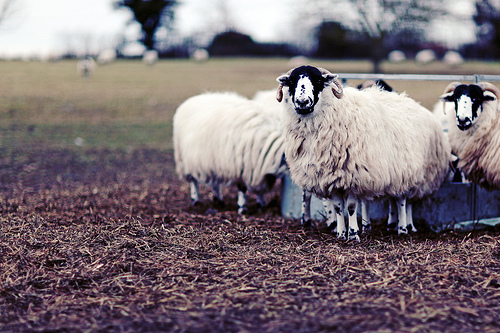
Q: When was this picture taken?
A: During the day.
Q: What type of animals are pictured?
A: Sheep.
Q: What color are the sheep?
A: White.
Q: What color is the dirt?
A: Brown.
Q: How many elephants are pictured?
A: Zero.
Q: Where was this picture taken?
A: In a field.